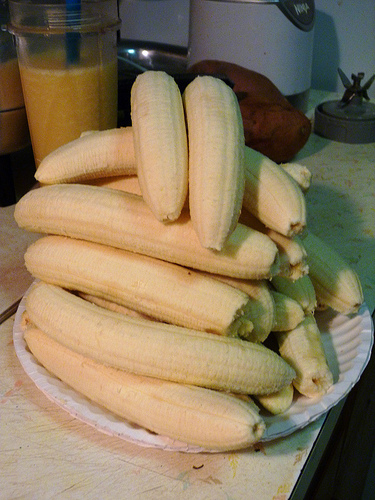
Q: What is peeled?
A: The bananas.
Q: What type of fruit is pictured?
A: Bananas.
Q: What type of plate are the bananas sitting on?
A: A paper plate.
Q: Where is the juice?
A: In cup.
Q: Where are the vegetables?
A: On counter.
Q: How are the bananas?
A: Peeled.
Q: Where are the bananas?
A: On plates.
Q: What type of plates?
A: Paper.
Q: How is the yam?
A: Raw.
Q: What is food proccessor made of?
A: Glass.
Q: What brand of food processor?
A: Ninja.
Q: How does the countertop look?
A: It has a floral leaf pattern.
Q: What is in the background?
A: A large sweet potato.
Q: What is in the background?
A: A white blender.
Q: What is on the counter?
A: A white paper plate.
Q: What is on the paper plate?
A: A stack of bananas.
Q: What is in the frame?
A: A stainless steel sink.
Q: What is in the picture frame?
A: A tan countertop.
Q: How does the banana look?
A: It is ripe.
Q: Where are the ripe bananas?
A: On the white plate.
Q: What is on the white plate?
A: Bananas.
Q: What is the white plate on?
A: The counter.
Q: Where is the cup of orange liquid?
A: Behind the plate.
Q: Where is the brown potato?
A: On the counter.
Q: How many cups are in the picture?
A: One.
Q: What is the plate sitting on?
A: A counter.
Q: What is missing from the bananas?
A: Their peels.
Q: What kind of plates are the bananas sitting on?
A: Paper.